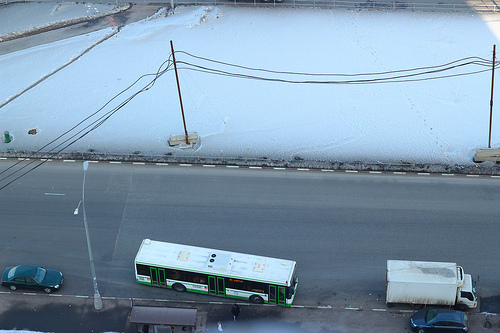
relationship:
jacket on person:
[230, 307, 240, 318] [229, 302, 241, 324]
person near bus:
[228, 303, 240, 323] [132, 225, 303, 304]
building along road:
[125, 305, 207, 330] [165, 168, 493, 238]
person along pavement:
[482, 313, 494, 328] [0, 156, 500, 333]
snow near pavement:
[0, 8, 498, 168] [0, 156, 500, 333]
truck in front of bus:
[386, 259, 478, 312] [133, 238, 299, 307]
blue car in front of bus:
[410, 308, 469, 333] [133, 238, 299, 307]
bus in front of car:
[133, 238, 299, 307] [0, 265, 65, 294]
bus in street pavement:
[133, 238, 299, 307] [0, 156, 500, 333]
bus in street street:
[133, 238, 299, 307] [116, 163, 421, 255]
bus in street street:
[127, 222, 309, 310] [2, 153, 499, 310]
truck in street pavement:
[386, 257, 480, 312] [0, 156, 500, 333]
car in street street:
[1, 262, 66, 295] [3, 162, 495, 302]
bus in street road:
[133, 238, 299, 307] [2, 154, 499, 311]